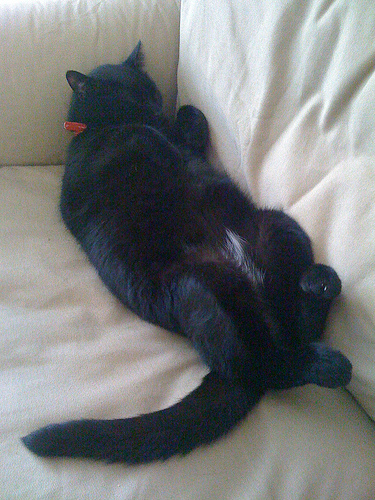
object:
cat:
[20, 40, 353, 465]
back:
[59, 150, 169, 323]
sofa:
[0, 0, 375, 498]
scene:
[0, 0, 375, 499]